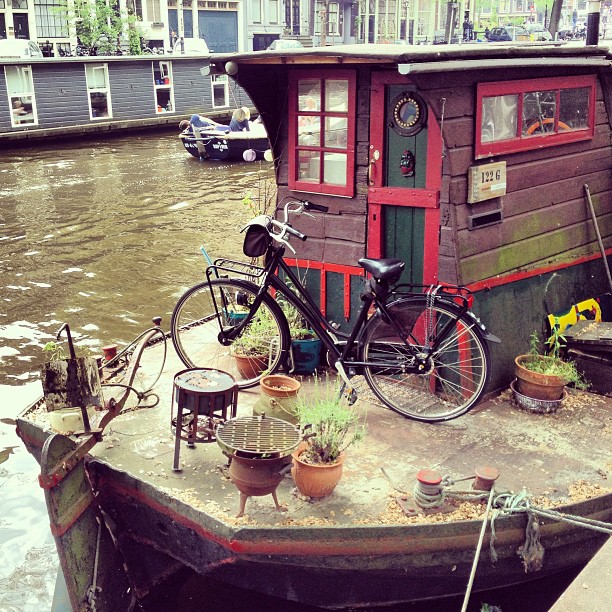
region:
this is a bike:
[167, 188, 515, 445]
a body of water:
[9, 124, 278, 368]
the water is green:
[5, 114, 307, 388]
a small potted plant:
[275, 369, 370, 542]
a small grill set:
[205, 403, 308, 533]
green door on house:
[349, 66, 459, 370]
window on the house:
[464, 75, 610, 160]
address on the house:
[461, 149, 523, 218]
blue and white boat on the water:
[177, 101, 267, 164]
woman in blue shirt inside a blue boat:
[224, 106, 251, 133]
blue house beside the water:
[1, 1, 176, 145]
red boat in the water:
[14, 35, 607, 610]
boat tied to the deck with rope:
[11, 36, 609, 609]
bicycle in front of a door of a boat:
[171, 71, 502, 425]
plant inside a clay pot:
[507, 314, 589, 414]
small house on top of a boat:
[203, 43, 609, 411]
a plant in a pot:
[288, 385, 349, 496]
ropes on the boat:
[432, 486, 603, 538]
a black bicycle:
[170, 233, 494, 417]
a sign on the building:
[462, 168, 503, 212]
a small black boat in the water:
[168, 111, 264, 159]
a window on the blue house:
[153, 65, 179, 110]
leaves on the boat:
[528, 468, 597, 511]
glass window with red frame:
[472, 74, 597, 159]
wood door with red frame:
[365, 71, 441, 393]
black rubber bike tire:
[362, 303, 488, 423]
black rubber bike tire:
[170, 278, 289, 389]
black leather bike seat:
[357, 255, 405, 282]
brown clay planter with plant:
[512, 318, 570, 408]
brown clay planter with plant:
[273, 371, 365, 498]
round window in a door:
[392, 92, 426, 136]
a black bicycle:
[168, 215, 486, 415]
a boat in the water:
[175, 113, 277, 153]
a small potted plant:
[516, 332, 572, 401]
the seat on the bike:
[357, 250, 401, 282]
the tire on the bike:
[172, 279, 288, 382]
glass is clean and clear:
[297, 78, 322, 113]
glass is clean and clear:
[323, 149, 347, 187]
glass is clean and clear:
[297, 149, 323, 184]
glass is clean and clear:
[214, 69, 229, 105]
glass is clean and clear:
[156, 60, 173, 112]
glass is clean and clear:
[80, 65, 113, 116]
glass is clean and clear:
[4, 67, 37, 125]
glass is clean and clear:
[34, 6, 66, 40]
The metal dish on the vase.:
[211, 412, 299, 453]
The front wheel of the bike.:
[160, 272, 287, 383]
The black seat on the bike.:
[353, 252, 406, 291]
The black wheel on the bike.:
[359, 293, 505, 428]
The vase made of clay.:
[290, 448, 348, 496]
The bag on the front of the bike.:
[240, 205, 267, 256]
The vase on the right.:
[509, 350, 577, 410]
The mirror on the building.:
[385, 94, 427, 134]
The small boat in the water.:
[179, 106, 275, 168]